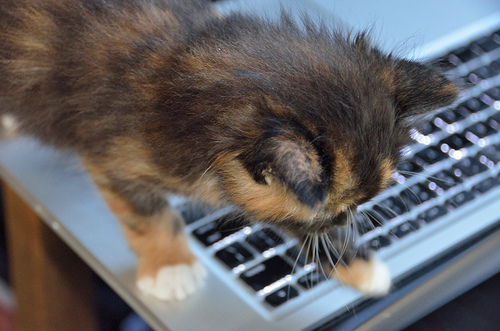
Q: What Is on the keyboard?
A: A kitty.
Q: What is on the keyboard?
A: White paws.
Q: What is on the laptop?
A: A kitty.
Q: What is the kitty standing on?
A: A kitten.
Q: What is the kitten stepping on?
A: A keyboard.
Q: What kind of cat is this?
A: Calico.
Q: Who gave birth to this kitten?
A: Mother cat.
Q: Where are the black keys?
A: Keyboard.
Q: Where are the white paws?
A: The kitten's feet.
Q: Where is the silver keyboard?
A: Under the kitten.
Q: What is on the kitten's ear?
A: Fur.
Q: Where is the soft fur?
A: On the kitten.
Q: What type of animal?
A: A cat.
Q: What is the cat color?
A: Brown and black.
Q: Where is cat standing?
A: On a laptop.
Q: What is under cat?
A: Keys.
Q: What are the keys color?
A: Black.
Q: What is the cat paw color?
A: White.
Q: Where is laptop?
A: On desk.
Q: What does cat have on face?
A: Whiskers.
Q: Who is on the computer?
A: A kitten.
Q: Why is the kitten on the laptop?
A: Walking.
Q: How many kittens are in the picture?
A: One.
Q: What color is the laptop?
A: Silver.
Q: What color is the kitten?
A: Black and orange.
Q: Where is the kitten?
A: Walking on the laptop.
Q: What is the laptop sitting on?
A: A table.